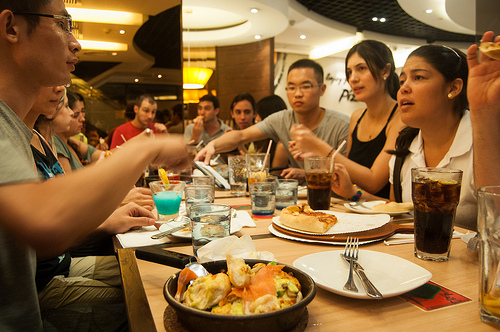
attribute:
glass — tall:
[411, 165, 458, 262]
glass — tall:
[476, 184, 498, 329]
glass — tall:
[302, 149, 334, 207]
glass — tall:
[188, 200, 233, 255]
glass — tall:
[244, 150, 268, 187]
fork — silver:
[341, 234, 363, 295]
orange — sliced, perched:
[150, 167, 169, 186]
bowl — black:
[157, 251, 320, 330]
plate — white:
[293, 225, 431, 299]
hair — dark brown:
[353, 39, 398, 88]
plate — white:
[291, 240, 441, 314]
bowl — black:
[142, 257, 330, 329]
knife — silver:
[344, 248, 381, 300]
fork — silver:
[343, 235, 358, 291]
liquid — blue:
[149, 190, 183, 216]